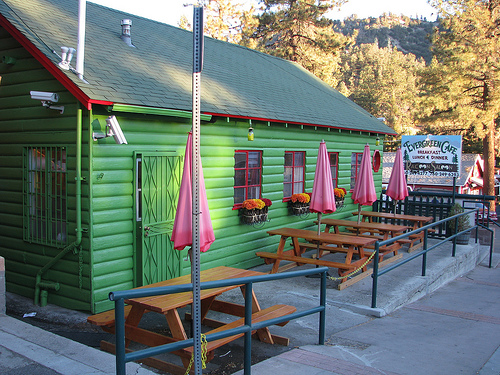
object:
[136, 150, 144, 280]
cracked open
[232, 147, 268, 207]
window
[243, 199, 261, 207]
flowers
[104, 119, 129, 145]
camera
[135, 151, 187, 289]
door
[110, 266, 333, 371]
railing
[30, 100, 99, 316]
pipe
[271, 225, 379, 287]
picnic table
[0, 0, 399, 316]
building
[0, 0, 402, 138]
roof